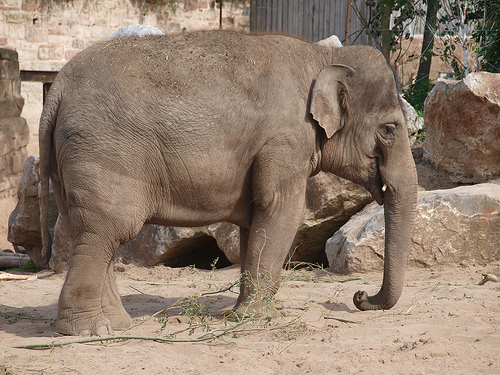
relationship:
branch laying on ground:
[14, 227, 331, 354] [0, 258, 500, 373]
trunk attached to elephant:
[329, 176, 470, 351] [38, 30, 416, 335]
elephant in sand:
[38, 30, 416, 335] [2, 248, 493, 373]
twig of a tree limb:
[21, 240, 328, 356] [13, 328, 175, 353]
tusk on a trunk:
[375, 178, 392, 200] [341, 158, 423, 337]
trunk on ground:
[351, 159, 419, 311] [0, 258, 500, 373]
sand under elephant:
[210, 293, 444, 368] [148, 85, 315, 179]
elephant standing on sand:
[38, 30, 416, 335] [7, 260, 490, 368]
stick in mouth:
[382, 181, 388, 195] [363, 150, 392, 213]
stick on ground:
[14, 253, 336, 354] [21, 269, 481, 357]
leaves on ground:
[178, 290, 237, 342] [21, 269, 481, 357]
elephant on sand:
[38, 30, 416, 335] [7, 260, 490, 368]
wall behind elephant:
[2, 4, 484, 173] [38, 30, 416, 335]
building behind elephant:
[0, 4, 263, 259] [39, 36, 407, 313]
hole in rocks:
[159, 231, 231, 269] [121, 154, 373, 266]